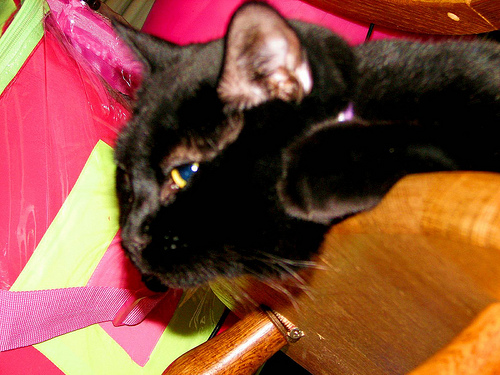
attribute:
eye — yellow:
[170, 160, 201, 184]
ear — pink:
[221, 2, 310, 103]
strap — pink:
[8, 285, 174, 349]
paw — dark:
[283, 124, 374, 224]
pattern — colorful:
[2, 5, 230, 372]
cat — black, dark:
[109, 14, 484, 292]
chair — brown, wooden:
[156, 170, 480, 370]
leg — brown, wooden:
[172, 312, 306, 371]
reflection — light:
[165, 154, 205, 188]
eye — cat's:
[154, 147, 213, 193]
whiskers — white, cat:
[182, 230, 331, 314]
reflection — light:
[244, 323, 276, 358]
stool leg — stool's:
[170, 150, 484, 370]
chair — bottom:
[311, 209, 475, 341]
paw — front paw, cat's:
[277, 103, 399, 243]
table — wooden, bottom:
[252, 175, 474, 373]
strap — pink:
[0, 283, 156, 361]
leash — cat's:
[1, 243, 174, 343]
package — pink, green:
[1, 1, 256, 372]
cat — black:
[99, 14, 480, 362]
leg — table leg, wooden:
[156, 317, 294, 369]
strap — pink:
[0, 270, 175, 348]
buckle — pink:
[112, 280, 177, 329]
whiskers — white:
[161, 248, 348, 318]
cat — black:
[92, 5, 481, 264]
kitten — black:
[81, 10, 484, 315]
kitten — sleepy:
[82, 10, 472, 281]